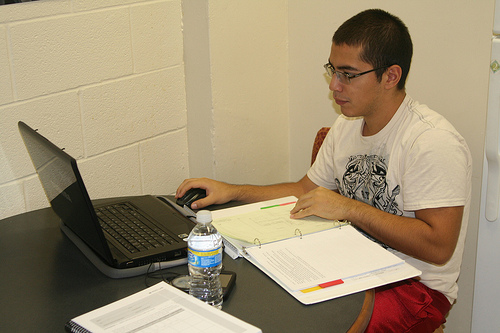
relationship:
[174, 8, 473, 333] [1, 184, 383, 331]
man working table.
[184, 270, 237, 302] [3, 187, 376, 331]
cell phone on table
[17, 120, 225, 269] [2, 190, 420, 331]
laptop on table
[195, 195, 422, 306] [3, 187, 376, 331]
booklet on table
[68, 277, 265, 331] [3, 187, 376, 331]
booklet on table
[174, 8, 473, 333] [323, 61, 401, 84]
man wearing eyeglasses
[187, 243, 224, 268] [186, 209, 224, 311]
label on bottle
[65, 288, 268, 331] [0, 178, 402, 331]
book stack on table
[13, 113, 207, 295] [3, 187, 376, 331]
laptop on table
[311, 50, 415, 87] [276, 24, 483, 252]
eyeglasses on man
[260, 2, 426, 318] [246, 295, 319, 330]
man on table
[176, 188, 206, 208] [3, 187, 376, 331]
mouse on table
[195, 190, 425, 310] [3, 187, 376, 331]
booklet on table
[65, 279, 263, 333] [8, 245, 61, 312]
booklet on table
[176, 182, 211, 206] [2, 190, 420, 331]
mouse on table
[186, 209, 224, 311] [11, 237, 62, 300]
bottle on table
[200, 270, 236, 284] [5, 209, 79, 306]
cell phone on table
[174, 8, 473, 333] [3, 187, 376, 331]
man sitting at table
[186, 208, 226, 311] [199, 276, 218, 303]
bottle of water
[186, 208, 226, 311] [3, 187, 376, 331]
bottle on table